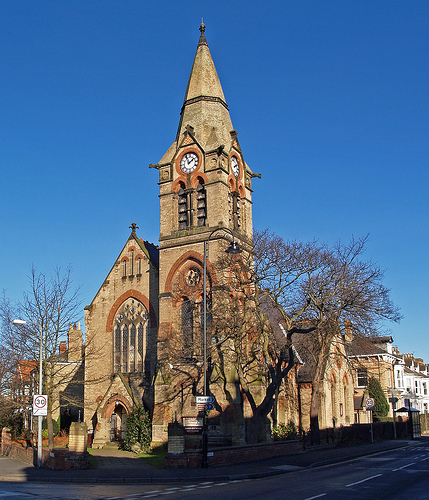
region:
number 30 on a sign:
[35, 397, 45, 403]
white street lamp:
[11, 313, 45, 467]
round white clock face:
[177, 149, 203, 175]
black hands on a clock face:
[184, 154, 194, 165]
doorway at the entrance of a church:
[104, 394, 127, 441]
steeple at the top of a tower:
[197, 13, 206, 28]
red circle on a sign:
[34, 395, 46, 406]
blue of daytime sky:
[1, 1, 427, 357]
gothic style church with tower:
[84, 19, 357, 452]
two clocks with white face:
[178, 147, 242, 177]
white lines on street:
[113, 442, 427, 498]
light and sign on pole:
[14, 318, 48, 468]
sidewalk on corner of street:
[1, 438, 406, 482]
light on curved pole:
[201, 226, 241, 396]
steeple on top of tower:
[174, 23, 240, 148]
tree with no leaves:
[170, 232, 401, 438]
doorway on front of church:
[93, 373, 141, 450]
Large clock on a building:
[177, 152, 196, 174]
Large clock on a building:
[228, 158, 245, 175]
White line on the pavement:
[198, 474, 213, 483]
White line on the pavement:
[181, 478, 195, 489]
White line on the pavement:
[165, 483, 174, 492]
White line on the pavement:
[145, 486, 157, 493]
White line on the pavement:
[214, 479, 236, 495]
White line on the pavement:
[195, 480, 210, 495]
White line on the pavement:
[175, 485, 198, 494]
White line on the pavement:
[335, 452, 400, 498]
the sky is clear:
[281, 99, 379, 159]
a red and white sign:
[29, 392, 50, 414]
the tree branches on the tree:
[318, 275, 384, 312]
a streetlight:
[215, 225, 241, 258]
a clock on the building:
[172, 150, 198, 169]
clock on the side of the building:
[228, 141, 242, 178]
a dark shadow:
[212, 400, 270, 449]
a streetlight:
[5, 317, 35, 326]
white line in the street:
[331, 471, 392, 483]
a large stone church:
[31, 16, 374, 455]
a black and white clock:
[176, 151, 199, 173]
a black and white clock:
[229, 156, 239, 174]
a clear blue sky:
[0, 0, 427, 360]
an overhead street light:
[9, 318, 40, 330]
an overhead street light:
[206, 223, 240, 254]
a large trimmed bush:
[363, 376, 389, 417]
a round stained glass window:
[183, 265, 200, 284]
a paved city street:
[6, 436, 427, 497]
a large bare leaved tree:
[0, 264, 108, 460]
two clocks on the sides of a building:
[181, 153, 240, 177]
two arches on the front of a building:
[327, 367, 352, 427]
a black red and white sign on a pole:
[34, 394, 47, 415]